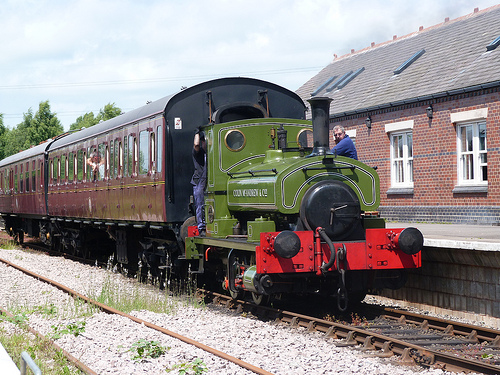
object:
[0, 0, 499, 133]
sky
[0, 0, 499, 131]
clouds